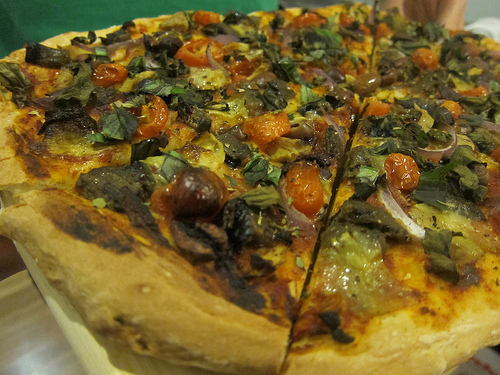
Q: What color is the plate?
A: White.